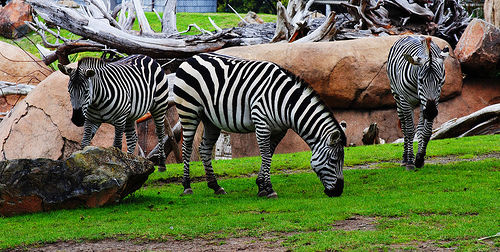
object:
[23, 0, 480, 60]
dead tree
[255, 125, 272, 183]
leg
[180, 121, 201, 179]
leg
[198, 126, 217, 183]
leg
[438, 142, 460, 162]
ground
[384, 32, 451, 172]
zebra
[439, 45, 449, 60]
ears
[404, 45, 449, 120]
head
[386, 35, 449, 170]
animal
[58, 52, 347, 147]
stripe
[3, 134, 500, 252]
grass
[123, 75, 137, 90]
fur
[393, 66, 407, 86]
fur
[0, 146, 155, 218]
rock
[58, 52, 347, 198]
animal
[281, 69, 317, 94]
mane